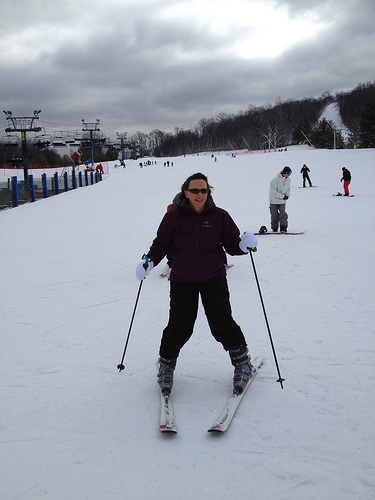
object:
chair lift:
[3, 107, 140, 167]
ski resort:
[0, 82, 373, 498]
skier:
[136, 172, 258, 397]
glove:
[238, 232, 258, 254]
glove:
[136, 255, 154, 281]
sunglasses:
[185, 188, 209, 194]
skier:
[269, 165, 292, 232]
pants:
[270, 204, 288, 231]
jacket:
[269, 173, 290, 204]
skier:
[340, 167, 351, 196]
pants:
[343, 181, 350, 193]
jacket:
[342, 169, 351, 180]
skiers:
[139, 163, 142, 168]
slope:
[0, 147, 374, 500]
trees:
[143, 129, 165, 156]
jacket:
[147, 192, 247, 282]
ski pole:
[118, 262, 148, 372]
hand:
[136, 258, 153, 279]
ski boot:
[158, 355, 176, 390]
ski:
[158, 362, 178, 434]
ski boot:
[230, 345, 251, 388]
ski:
[207, 354, 266, 434]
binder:
[158, 358, 171, 369]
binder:
[230, 347, 249, 361]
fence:
[0, 171, 102, 215]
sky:
[0, 0, 375, 135]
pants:
[159, 277, 245, 360]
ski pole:
[249, 250, 284, 389]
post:
[13, 177, 17, 207]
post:
[29, 175, 35, 201]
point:
[280, 382, 283, 389]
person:
[300, 164, 312, 188]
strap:
[142, 254, 152, 263]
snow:
[319, 103, 353, 143]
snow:
[0, 142, 374, 500]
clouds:
[0, 0, 375, 132]